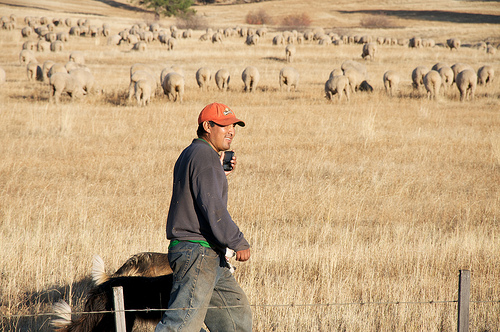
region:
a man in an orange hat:
[152, 100, 252, 328]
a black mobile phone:
[220, 147, 230, 167]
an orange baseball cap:
[195, 100, 245, 125]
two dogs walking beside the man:
[41, 250, 231, 330]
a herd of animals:
[0, 11, 495, 97]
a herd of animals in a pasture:
[0, 10, 495, 100]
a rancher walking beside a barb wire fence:
[2, 101, 499, 329]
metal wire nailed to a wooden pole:
[1, 298, 498, 320]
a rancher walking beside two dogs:
[47, 102, 254, 330]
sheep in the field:
[322, 76, 352, 101]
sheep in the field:
[275, 57, 310, 105]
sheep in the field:
[238, 65, 264, 97]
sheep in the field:
[212, 65, 237, 102]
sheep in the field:
[185, 55, 215, 99]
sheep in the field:
[372, 68, 406, 99]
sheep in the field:
[163, 79, 187, 106]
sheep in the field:
[407, 68, 446, 101]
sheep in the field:
[42, 73, 90, 102]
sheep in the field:
[281, 43, 298, 55]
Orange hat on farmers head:
[196, 102, 244, 123]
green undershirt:
[163, 235, 221, 251]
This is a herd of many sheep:
[5, 15, 495, 98]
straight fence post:
[456, 268, 472, 328]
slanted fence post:
[106, 281, 131, 327]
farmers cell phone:
[221, 150, 232, 170]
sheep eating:
[37, 67, 97, 107]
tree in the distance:
[135, 1, 210, 26]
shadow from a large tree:
[345, 6, 492, 21]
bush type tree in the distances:
[243, 13, 313, 30]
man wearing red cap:
[204, 107, 218, 115]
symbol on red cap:
[221, 102, 232, 119]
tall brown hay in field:
[376, 203, 403, 243]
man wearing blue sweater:
[179, 177, 200, 206]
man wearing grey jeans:
[188, 270, 203, 300]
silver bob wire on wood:
[136, 304, 159, 314]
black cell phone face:
[225, 152, 232, 167]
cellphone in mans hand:
[218, 147, 239, 175]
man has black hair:
[195, 127, 205, 137]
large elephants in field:
[136, 58, 297, 100]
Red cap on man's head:
[198, 100, 247, 124]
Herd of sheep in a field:
[2, 4, 497, 102]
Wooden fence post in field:
[457, 267, 469, 329]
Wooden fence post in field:
[110, 290, 127, 330]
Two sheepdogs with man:
[53, 248, 172, 328]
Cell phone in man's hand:
[219, 149, 234, 171]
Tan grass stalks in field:
[285, 225, 395, 289]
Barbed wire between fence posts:
[132, 298, 454, 313]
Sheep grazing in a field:
[322, 78, 349, 100]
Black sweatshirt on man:
[164, 140, 246, 249]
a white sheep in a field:
[125, 71, 162, 103]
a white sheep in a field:
[48, 71, 93, 100]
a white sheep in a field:
[26, 59, 44, 84]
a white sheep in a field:
[193, 64, 215, 89]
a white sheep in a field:
[239, 69, 260, 91]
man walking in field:
[137, 84, 269, 329]